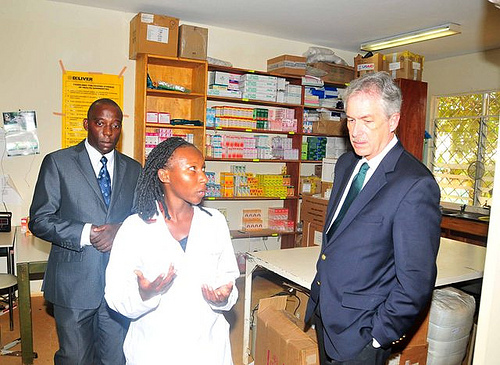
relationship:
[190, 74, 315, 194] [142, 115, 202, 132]
objects on shelf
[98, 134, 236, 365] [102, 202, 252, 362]
people wears coat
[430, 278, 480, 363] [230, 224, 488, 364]
bundle under table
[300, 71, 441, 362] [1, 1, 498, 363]
man in room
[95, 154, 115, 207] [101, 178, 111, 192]
blue tie has spots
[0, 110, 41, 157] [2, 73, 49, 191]
poster on wall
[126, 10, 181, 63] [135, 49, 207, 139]
box on shelf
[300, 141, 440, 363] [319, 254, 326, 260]
suit has button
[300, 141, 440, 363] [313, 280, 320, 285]
suit has button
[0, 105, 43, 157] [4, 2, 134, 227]
poster on wall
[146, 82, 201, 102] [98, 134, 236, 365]
shelf behind people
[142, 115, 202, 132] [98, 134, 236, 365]
shelf behind people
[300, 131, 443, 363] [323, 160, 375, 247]
man wears blue tie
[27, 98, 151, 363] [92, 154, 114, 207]
man wears blue tie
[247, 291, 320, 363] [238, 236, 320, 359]
box under table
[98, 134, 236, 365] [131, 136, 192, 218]
people has dark hair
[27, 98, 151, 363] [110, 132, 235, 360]
man behind woman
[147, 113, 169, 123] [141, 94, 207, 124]
boxes on shelf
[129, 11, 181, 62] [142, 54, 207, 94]
box on shelf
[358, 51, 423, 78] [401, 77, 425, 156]
boxes on shelf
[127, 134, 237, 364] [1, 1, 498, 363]
people in room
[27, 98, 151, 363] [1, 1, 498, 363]
man in room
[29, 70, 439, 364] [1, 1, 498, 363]
three people in room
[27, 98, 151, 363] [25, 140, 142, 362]
man wears suit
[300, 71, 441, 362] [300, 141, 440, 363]
man wears suit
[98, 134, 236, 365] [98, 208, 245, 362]
people has white shirt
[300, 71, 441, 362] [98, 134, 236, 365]
man standing in people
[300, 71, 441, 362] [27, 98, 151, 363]
man standing in man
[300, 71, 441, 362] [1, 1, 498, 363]
man standing in room